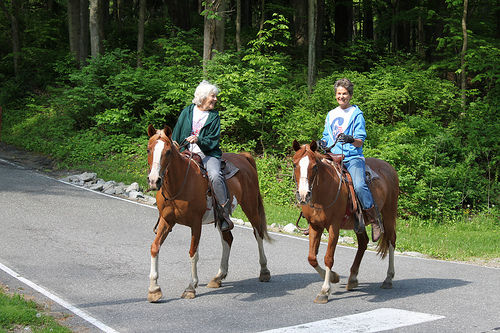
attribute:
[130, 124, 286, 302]
horse — brown, white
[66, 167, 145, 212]
stone — grey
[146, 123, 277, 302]
chestnut horse — Chestnut color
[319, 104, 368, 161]
jacket — blue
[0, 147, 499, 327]
road — paved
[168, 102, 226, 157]
cardigan — green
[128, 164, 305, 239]
horse — Chestnut color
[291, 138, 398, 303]
horse — white, brown, Chestnut color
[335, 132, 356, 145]
gloves — black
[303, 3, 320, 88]
tree — grey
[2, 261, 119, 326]
line — white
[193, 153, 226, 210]
pants — gray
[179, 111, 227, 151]
jacket — green, zip up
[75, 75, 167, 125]
bushes — dark green, leafy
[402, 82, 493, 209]
bushes — dark green, leafy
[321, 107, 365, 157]
shirt — blue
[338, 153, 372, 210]
pants — blue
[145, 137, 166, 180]
blaze — white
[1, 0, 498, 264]
forest — green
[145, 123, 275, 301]
horse — white, brown, brown and white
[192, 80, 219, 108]
hair — white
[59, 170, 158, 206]
rocks — gray